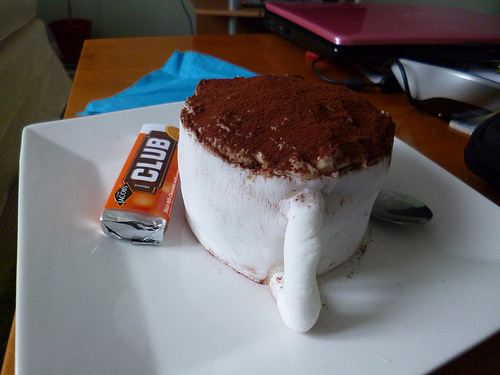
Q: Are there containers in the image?
A: No, there are no containers.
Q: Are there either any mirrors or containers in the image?
A: No, there are no containers or mirrors.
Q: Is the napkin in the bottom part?
A: No, the napkin is in the top of the image.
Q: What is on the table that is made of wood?
A: The napkin is on the table.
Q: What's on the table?
A: The napkin is on the table.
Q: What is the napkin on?
A: The napkin is on the table.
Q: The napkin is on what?
A: The napkin is on the table.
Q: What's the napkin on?
A: The napkin is on the table.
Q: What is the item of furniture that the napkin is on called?
A: The piece of furniture is a table.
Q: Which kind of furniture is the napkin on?
A: The napkin is on the table.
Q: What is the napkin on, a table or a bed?
A: The napkin is on a table.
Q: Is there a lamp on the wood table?
A: No, there is a napkin on the table.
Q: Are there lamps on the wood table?
A: No, there is a napkin on the table.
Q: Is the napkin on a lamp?
A: No, the napkin is on a table.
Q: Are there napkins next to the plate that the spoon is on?
A: Yes, there is a napkin next to the plate.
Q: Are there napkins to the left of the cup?
A: Yes, there is a napkin to the left of the cup.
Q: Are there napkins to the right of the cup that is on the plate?
A: No, the napkin is to the left of the cup.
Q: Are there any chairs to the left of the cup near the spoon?
A: No, there is a napkin to the left of the cup.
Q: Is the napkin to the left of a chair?
A: No, the napkin is to the left of a cup.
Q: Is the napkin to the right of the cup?
A: No, the napkin is to the left of the cup.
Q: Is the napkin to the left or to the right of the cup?
A: The napkin is to the left of the cup.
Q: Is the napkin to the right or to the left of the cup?
A: The napkin is to the left of the cup.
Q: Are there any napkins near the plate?
A: Yes, there is a napkin near the plate.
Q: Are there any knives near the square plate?
A: No, there is a napkin near the plate.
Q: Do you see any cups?
A: Yes, there is a cup.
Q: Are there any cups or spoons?
A: Yes, there is a cup.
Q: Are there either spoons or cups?
A: Yes, there is a cup.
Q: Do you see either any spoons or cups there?
A: Yes, there is a cup.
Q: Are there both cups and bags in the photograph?
A: No, there is a cup but no bags.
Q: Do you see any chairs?
A: No, there are no chairs.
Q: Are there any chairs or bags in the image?
A: No, there are no chairs or bags.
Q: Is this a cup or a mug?
A: This is a cup.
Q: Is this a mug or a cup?
A: This is a cup.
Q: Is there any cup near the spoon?
A: Yes, there is a cup near the spoon.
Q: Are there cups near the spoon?
A: Yes, there is a cup near the spoon.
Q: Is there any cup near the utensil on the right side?
A: Yes, there is a cup near the spoon.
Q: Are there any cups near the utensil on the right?
A: Yes, there is a cup near the spoon.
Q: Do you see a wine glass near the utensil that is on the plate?
A: No, there is a cup near the spoon.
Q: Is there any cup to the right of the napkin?
A: Yes, there is a cup to the right of the napkin.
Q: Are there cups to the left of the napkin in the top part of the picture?
A: No, the cup is to the right of the napkin.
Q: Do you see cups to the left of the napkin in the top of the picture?
A: No, the cup is to the right of the napkin.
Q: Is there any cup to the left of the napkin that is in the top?
A: No, the cup is to the right of the napkin.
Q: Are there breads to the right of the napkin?
A: No, there is a cup to the right of the napkin.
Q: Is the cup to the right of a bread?
A: No, the cup is to the right of the napkin.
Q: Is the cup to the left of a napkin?
A: No, the cup is to the right of a napkin.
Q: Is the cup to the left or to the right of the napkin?
A: The cup is to the right of the napkin.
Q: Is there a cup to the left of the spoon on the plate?
A: Yes, there is a cup to the left of the spoon.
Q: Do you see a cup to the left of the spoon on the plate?
A: Yes, there is a cup to the left of the spoon.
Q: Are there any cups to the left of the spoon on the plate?
A: Yes, there is a cup to the left of the spoon.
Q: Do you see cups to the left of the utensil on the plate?
A: Yes, there is a cup to the left of the spoon.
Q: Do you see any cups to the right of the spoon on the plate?
A: No, the cup is to the left of the spoon.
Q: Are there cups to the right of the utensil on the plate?
A: No, the cup is to the left of the spoon.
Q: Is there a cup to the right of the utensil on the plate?
A: No, the cup is to the left of the spoon.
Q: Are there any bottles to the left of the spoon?
A: No, there is a cup to the left of the spoon.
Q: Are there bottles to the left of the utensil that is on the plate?
A: No, there is a cup to the left of the spoon.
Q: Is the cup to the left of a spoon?
A: Yes, the cup is to the left of a spoon.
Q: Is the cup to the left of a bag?
A: No, the cup is to the left of a spoon.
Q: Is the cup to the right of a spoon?
A: No, the cup is to the left of a spoon.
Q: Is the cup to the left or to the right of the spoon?
A: The cup is to the left of the spoon.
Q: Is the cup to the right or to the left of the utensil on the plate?
A: The cup is to the left of the spoon.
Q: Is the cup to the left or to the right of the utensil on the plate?
A: The cup is to the left of the spoon.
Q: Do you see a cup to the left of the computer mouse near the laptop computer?
A: Yes, there is a cup to the left of the mouse.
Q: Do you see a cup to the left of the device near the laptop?
A: Yes, there is a cup to the left of the mouse.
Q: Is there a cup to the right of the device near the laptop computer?
A: No, the cup is to the left of the mouse.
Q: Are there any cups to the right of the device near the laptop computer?
A: No, the cup is to the left of the mouse.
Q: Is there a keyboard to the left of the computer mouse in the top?
A: No, there is a cup to the left of the computer mouse.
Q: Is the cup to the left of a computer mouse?
A: Yes, the cup is to the left of a computer mouse.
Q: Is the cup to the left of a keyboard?
A: No, the cup is to the left of a computer mouse.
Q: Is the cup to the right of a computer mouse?
A: No, the cup is to the left of a computer mouse.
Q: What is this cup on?
A: The cup is on the plate.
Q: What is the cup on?
A: The cup is on the plate.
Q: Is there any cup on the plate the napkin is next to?
A: Yes, there is a cup on the plate.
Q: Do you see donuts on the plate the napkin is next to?
A: No, there is a cup on the plate.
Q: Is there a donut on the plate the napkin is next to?
A: No, there is a cup on the plate.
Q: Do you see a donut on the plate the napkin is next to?
A: No, there is a cup on the plate.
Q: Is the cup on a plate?
A: Yes, the cup is on a plate.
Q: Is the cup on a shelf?
A: No, the cup is on a plate.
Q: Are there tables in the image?
A: Yes, there is a table.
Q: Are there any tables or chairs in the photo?
A: Yes, there is a table.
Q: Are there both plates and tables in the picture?
A: Yes, there are both a table and a plate.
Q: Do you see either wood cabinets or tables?
A: Yes, there is a wood table.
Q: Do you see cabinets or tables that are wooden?
A: Yes, the table is wooden.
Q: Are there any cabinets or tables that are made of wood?
A: Yes, the table is made of wood.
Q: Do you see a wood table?
A: Yes, there is a table that is made of wood.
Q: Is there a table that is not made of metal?
A: Yes, there is a table that is made of wood.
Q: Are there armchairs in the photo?
A: No, there are no armchairs.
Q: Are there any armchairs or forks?
A: No, there are no armchairs or forks.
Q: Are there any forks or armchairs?
A: No, there are no armchairs or forks.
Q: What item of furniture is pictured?
A: The piece of furniture is a table.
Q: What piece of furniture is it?
A: The piece of furniture is a table.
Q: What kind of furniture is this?
A: This is a table.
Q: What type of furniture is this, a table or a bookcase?
A: This is a table.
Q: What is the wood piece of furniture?
A: The piece of furniture is a table.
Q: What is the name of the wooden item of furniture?
A: The piece of furniture is a table.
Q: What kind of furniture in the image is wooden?
A: The furniture is a table.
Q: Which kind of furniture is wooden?
A: The furniture is a table.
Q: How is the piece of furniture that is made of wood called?
A: The piece of furniture is a table.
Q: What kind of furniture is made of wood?
A: The furniture is a table.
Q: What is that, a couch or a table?
A: That is a table.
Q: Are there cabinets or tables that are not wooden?
A: No, there is a table but it is wooden.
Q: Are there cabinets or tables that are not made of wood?
A: No, there is a table but it is made of wood.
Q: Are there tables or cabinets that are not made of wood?
A: No, there is a table but it is made of wood.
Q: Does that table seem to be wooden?
A: Yes, the table is wooden.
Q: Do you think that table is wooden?
A: Yes, the table is wooden.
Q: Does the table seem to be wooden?
A: Yes, the table is wooden.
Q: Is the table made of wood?
A: Yes, the table is made of wood.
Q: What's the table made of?
A: The table is made of wood.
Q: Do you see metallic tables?
A: No, there is a table but it is wooden.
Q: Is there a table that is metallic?
A: No, there is a table but it is wooden.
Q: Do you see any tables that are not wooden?
A: No, there is a table but it is wooden.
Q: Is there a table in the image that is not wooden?
A: No, there is a table but it is wooden.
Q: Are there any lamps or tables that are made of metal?
A: No, there is a table but it is made of wood.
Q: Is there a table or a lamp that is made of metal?
A: No, there is a table but it is made of wood.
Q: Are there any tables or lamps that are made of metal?
A: No, there is a table but it is made of wood.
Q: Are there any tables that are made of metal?
A: No, there is a table but it is made of wood.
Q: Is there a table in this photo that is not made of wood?
A: No, there is a table but it is made of wood.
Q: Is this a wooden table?
A: Yes, this is a wooden table.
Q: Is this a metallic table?
A: No, this is a wooden table.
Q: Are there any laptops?
A: Yes, there is a laptop.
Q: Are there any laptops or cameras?
A: Yes, there is a laptop.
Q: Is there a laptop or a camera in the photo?
A: Yes, there is a laptop.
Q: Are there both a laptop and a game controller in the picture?
A: No, there is a laptop but no game controllers.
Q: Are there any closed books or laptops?
A: Yes, there is a closed laptop.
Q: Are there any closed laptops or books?
A: Yes, there is a closed laptop.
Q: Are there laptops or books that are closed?
A: Yes, the laptop is closed.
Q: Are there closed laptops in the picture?
A: Yes, there is a closed laptop.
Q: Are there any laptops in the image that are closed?
A: Yes, there is a laptop that is closed.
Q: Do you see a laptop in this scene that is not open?
A: Yes, there is an closed laptop.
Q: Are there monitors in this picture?
A: No, there are no monitors.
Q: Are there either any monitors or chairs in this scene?
A: No, there are no monitors or chairs.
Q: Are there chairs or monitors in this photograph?
A: No, there are no monitors or chairs.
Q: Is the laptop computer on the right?
A: Yes, the laptop computer is on the right of the image.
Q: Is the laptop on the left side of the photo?
A: No, the laptop is on the right of the image.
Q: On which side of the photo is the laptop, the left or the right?
A: The laptop is on the right of the image.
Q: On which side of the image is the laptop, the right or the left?
A: The laptop is on the right of the image.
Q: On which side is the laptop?
A: The laptop is on the right of the image.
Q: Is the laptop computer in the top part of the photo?
A: Yes, the laptop computer is in the top of the image.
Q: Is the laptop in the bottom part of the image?
A: No, the laptop is in the top of the image.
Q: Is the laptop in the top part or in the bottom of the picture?
A: The laptop is in the top of the image.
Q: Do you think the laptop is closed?
A: Yes, the laptop is closed.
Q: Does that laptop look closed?
A: Yes, the laptop is closed.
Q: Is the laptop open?
A: No, the laptop is closed.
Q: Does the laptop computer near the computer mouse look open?
A: No, the laptop computer is closed.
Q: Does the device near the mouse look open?
A: No, the laptop computer is closed.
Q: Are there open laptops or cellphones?
A: No, there is a laptop but it is closed.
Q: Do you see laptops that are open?
A: No, there is a laptop but it is closed.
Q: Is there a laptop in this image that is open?
A: No, there is a laptop but it is closed.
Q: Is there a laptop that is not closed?
A: No, there is a laptop but it is closed.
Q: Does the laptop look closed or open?
A: The laptop is closed.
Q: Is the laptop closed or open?
A: The laptop is closed.